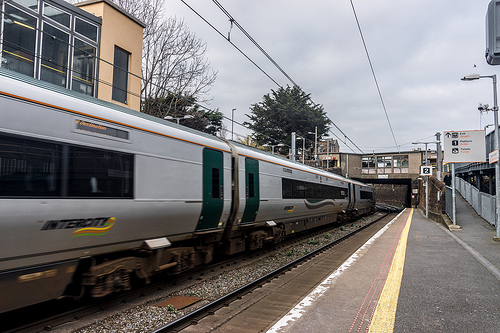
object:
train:
[1, 66, 378, 314]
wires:
[0, 0, 402, 158]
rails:
[2, 202, 407, 332]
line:
[378, 207, 416, 332]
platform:
[398, 208, 498, 332]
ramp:
[446, 181, 498, 269]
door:
[195, 146, 224, 230]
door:
[241, 156, 261, 223]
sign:
[443, 129, 487, 164]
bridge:
[308, 150, 446, 207]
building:
[1, 0, 145, 113]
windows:
[0, 0, 98, 97]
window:
[1, 1, 37, 77]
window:
[39, 1, 72, 87]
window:
[69, 12, 103, 97]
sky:
[357, 0, 461, 130]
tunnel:
[352, 177, 413, 208]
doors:
[195, 146, 262, 229]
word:
[38, 217, 117, 240]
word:
[283, 204, 296, 214]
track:
[158, 207, 409, 332]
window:
[0, 132, 135, 199]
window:
[281, 177, 348, 199]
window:
[360, 190, 373, 199]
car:
[1, 73, 234, 312]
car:
[229, 141, 354, 256]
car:
[352, 178, 378, 220]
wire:
[226, 14, 236, 41]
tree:
[243, 85, 335, 157]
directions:
[443, 129, 475, 155]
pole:
[456, 72, 499, 241]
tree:
[114, 0, 216, 120]